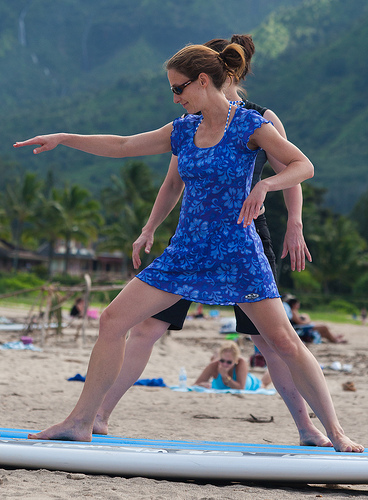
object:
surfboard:
[1, 448, 364, 486]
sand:
[3, 304, 367, 499]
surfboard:
[2, 424, 367, 457]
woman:
[195, 343, 273, 391]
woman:
[21, 43, 367, 453]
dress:
[136, 105, 286, 304]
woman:
[94, 34, 331, 447]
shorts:
[147, 211, 279, 333]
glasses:
[171, 73, 198, 95]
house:
[3, 235, 46, 272]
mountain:
[2, 1, 367, 216]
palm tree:
[46, 179, 100, 280]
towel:
[65, 371, 166, 388]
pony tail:
[220, 44, 249, 75]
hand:
[13, 129, 63, 155]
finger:
[34, 143, 53, 154]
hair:
[163, 43, 246, 84]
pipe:
[237, 413, 276, 425]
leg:
[68, 278, 181, 424]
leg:
[236, 300, 346, 434]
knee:
[97, 309, 112, 331]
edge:
[154, 312, 185, 333]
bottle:
[178, 364, 188, 390]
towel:
[170, 382, 279, 396]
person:
[287, 294, 351, 346]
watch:
[223, 375, 231, 385]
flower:
[188, 216, 209, 242]